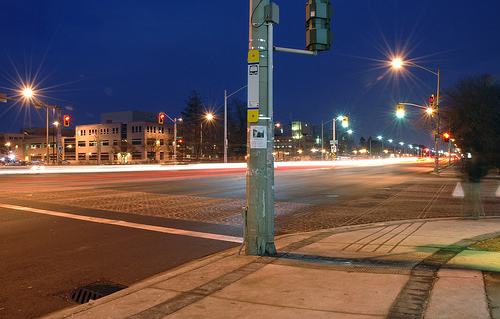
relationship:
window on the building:
[99, 124, 111, 140] [72, 104, 182, 160]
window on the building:
[119, 120, 128, 135] [74, 116, 187, 166]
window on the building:
[146, 121, 159, 136] [72, 122, 192, 162]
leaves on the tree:
[446, 92, 474, 149] [428, 70, 476, 184]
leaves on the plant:
[461, 99, 482, 125] [440, 72, 500, 183]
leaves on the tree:
[188, 94, 201, 112] [180, 83, 207, 156]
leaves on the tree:
[206, 111, 228, 160] [215, 104, 238, 158]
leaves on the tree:
[465, 106, 478, 154] [431, 78, 480, 178]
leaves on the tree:
[457, 95, 481, 137] [431, 78, 480, 178]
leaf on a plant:
[466, 110, 471, 113] [430, 78, 482, 176]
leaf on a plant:
[481, 107, 483, 109] [433, 80, 482, 173]